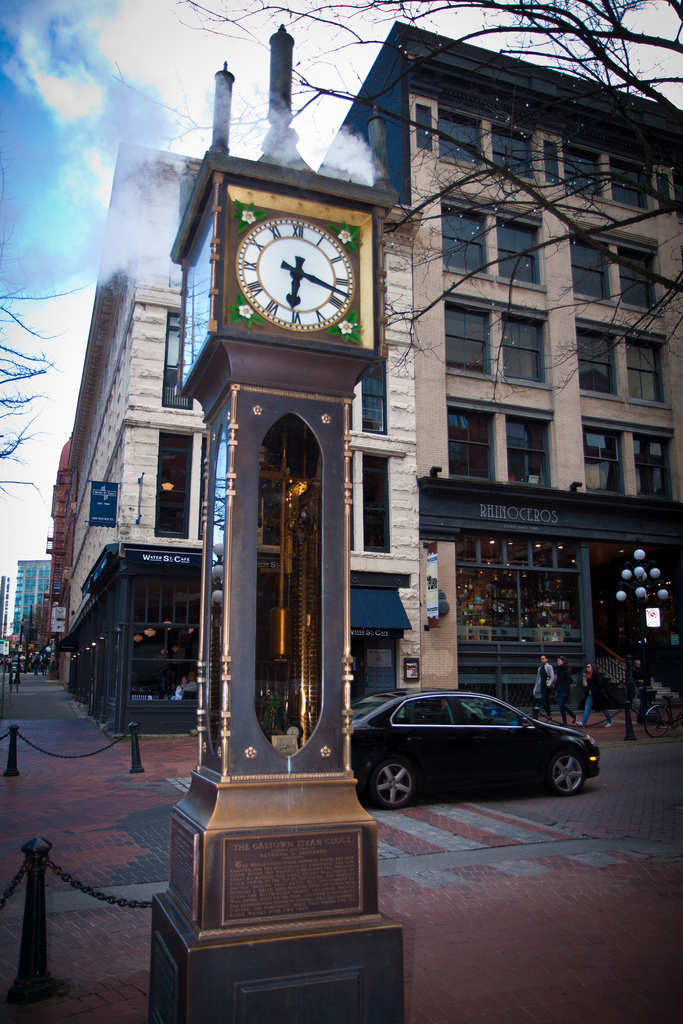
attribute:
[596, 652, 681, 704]
stairs — case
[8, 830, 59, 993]
post — black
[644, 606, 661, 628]
sign — parking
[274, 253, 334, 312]
hands — black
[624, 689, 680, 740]
bicycle — dark, colored, parked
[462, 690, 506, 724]
window —  clear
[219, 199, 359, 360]
clock — monument 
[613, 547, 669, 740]
street lamp —  street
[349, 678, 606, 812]
vehicle — black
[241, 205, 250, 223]
flower —  corner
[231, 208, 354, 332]
clock — round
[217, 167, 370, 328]
sign — silver, lettered, rhinoceros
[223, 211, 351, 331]
clock — ornate, steam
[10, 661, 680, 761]
sidewalk — long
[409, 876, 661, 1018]
ground — red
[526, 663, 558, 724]
outfit — black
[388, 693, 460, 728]
window — side 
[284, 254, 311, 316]
hands — black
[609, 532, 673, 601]
bulbs — white 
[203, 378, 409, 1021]
pedastal — black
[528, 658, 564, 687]
jacket — grey